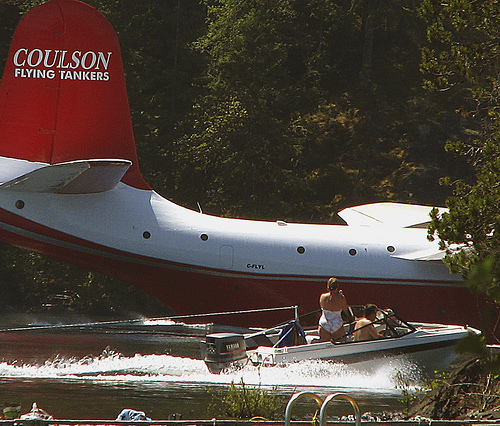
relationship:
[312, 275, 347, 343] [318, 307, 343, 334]
woman wearing bathing suit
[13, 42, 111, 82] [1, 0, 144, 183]
logo on tail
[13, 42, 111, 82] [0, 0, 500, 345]
logo on airplane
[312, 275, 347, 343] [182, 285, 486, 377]
woman riding in motorboat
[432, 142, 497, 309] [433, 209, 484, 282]
branches with green leaves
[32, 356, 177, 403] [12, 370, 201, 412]
water in a lake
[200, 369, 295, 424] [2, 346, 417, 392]
bush next to lake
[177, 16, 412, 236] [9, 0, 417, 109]
tree in background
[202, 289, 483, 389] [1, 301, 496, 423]
boat in river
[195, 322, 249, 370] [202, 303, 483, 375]
engine of a boat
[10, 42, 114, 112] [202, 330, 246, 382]
logo of black engine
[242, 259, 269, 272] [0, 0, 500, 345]
letters on side of airplane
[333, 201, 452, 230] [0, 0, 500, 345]
wing of airplane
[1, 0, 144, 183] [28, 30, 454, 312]
tail of airplane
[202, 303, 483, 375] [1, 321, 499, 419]
boat traveling in water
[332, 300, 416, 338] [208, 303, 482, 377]
windshield of boat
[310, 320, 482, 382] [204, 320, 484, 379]
stripe on boat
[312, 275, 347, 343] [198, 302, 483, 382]
woman standing in boat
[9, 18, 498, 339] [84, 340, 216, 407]
plane in water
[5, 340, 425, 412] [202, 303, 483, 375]
splash behind boat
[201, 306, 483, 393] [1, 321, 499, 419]
boat on water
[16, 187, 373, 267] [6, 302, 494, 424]
airplane on water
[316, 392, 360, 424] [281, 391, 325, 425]
handle on handle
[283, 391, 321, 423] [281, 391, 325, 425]
handle on handle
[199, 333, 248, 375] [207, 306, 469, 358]
engine on boat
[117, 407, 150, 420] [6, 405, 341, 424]
clothing on pier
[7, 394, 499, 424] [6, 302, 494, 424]
pier on water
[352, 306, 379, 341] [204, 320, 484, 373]
man driving boat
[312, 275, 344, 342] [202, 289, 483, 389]
woman standing in boat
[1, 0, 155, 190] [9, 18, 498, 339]
tail on plane